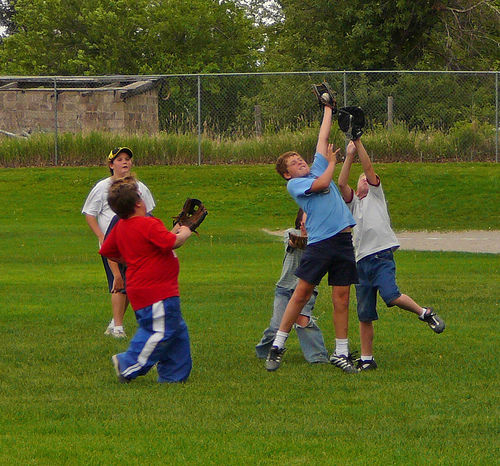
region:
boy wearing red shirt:
[87, 187, 194, 377]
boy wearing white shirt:
[338, 109, 449, 366]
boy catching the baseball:
[271, 85, 355, 372]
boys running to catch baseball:
[72, 77, 454, 377]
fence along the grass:
[3, 69, 497, 164]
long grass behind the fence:
[8, 126, 496, 157]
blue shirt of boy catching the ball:
[283, 157, 353, 239]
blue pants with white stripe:
[121, 293, 193, 385]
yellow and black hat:
[106, 147, 133, 161]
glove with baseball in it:
[313, 77, 334, 109]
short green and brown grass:
[207, 374, 249, 419]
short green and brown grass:
[286, 373, 319, 417]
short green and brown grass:
[356, 392, 407, 441]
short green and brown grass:
[2, 372, 55, 419]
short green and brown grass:
[29, 268, 71, 320]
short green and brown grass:
[206, 245, 238, 271]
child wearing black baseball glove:
[172, 191, 208, 236]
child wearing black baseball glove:
[305, 71, 340, 118]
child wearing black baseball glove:
[335, 100, 375, 135]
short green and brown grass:
[403, 178, 473, 225]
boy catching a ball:
[270, 78, 371, 384]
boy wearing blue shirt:
[290, 147, 365, 397]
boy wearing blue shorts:
[255, 141, 360, 386]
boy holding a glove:
[105, 175, 211, 400]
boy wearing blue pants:
[75, 175, 210, 385]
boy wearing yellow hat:
[100, 132, 141, 172]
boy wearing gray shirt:
[352, 140, 452, 377]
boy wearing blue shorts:
[355, 150, 445, 380]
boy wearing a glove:
[340, 98, 435, 349]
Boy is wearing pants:
[114, 290, 198, 385]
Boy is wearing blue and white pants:
[116, 292, 193, 385]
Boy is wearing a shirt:
[97, 216, 187, 314]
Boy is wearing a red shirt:
[95, 212, 182, 308]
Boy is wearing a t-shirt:
[98, 214, 187, 313]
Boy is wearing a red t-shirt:
[97, 215, 183, 312]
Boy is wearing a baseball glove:
[172, 194, 209, 232]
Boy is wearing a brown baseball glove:
[173, 196, 209, 231]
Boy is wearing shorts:
[292, 230, 364, 287]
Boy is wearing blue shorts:
[294, 228, 364, 289]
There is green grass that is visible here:
[428, 378, 454, 437]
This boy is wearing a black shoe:
[271, 327, 297, 402]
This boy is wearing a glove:
[183, 185, 207, 251]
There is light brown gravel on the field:
[473, 223, 485, 250]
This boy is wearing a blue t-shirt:
[297, 172, 348, 207]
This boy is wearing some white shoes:
[111, 317, 126, 357]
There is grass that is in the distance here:
[451, 127, 473, 168]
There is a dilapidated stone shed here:
[42, 76, 103, 148]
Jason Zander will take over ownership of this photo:
[111, 88, 389, 428]